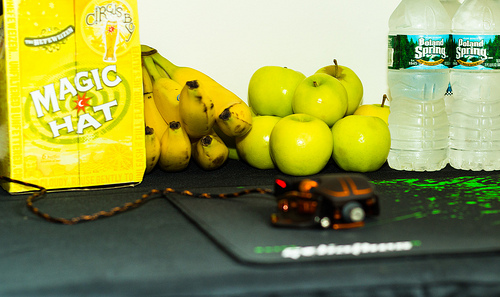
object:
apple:
[265, 114, 336, 178]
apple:
[247, 62, 305, 117]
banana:
[153, 71, 217, 141]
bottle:
[381, 1, 453, 173]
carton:
[0, 0, 148, 198]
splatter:
[374, 163, 499, 225]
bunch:
[133, 39, 256, 176]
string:
[3, 174, 276, 233]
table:
[2, 161, 495, 297]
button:
[343, 202, 367, 224]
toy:
[268, 161, 377, 238]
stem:
[331, 57, 343, 79]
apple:
[311, 57, 367, 115]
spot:
[193, 95, 208, 104]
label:
[384, 32, 454, 76]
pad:
[160, 165, 499, 266]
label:
[451, 32, 499, 74]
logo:
[18, 59, 137, 146]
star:
[66, 89, 95, 117]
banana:
[137, 84, 195, 172]